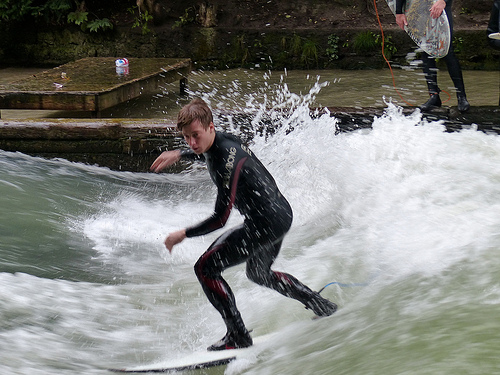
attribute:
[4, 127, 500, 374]
water — wavy, white, green, turbulent, brown, way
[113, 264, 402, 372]
surfboard — white, only edge, black rimmed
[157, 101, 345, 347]
person — wet, young, surfing, man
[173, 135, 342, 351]
wetsuit — black, red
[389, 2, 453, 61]
surfboard — part, partly missing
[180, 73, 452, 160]
splash — white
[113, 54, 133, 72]
bottle — plastic, discarded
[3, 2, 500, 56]
wall — stoney, mossy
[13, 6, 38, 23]
tree — invisible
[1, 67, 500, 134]
pavement — wet, stone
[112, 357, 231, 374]
edge — black